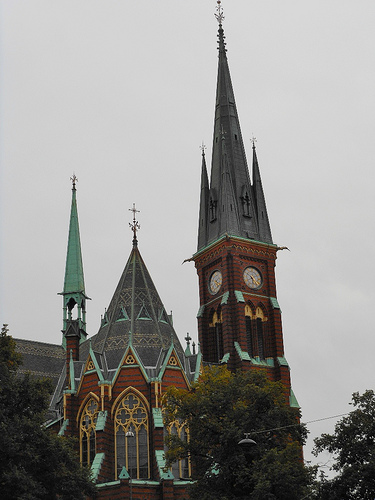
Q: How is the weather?
A: It is overcast.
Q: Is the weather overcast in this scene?
A: Yes, it is overcast.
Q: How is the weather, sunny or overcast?
A: It is overcast.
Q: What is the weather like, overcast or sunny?
A: It is overcast.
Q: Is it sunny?
A: No, it is overcast.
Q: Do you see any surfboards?
A: No, there are no surfboards.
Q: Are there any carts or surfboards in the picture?
A: No, there are no surfboards or carts.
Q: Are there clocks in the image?
A: Yes, there is a clock.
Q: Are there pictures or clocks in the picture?
A: Yes, there is a clock.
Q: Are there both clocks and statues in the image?
A: No, there is a clock but no statues.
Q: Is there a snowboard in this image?
A: No, there are no snowboards.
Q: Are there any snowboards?
A: No, there are no snowboards.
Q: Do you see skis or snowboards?
A: No, there are no snowboards or skis.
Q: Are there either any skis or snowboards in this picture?
A: No, there are no snowboards or skis.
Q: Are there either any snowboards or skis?
A: No, there are no snowboards or skis.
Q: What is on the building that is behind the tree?
A: The clock is on the building.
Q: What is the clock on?
A: The clock is on the building.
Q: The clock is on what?
A: The clock is on the building.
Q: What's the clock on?
A: The clock is on the building.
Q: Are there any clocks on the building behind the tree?
A: Yes, there is a clock on the building.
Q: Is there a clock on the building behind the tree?
A: Yes, there is a clock on the building.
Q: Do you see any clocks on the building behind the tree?
A: Yes, there is a clock on the building.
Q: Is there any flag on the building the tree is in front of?
A: No, there is a clock on the building.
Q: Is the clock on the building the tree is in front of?
A: Yes, the clock is on the building.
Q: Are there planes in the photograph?
A: No, there are no planes.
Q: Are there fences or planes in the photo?
A: No, there are no planes or fences.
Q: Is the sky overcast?
A: Yes, the sky is overcast.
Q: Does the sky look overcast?
A: Yes, the sky is overcast.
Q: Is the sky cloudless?
A: No, the sky is overcast.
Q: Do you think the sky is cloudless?
A: No, the sky is overcast.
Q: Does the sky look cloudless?
A: No, the sky is overcast.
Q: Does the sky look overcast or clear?
A: The sky is overcast.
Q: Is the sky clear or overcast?
A: The sky is overcast.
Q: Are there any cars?
A: No, there are no cars.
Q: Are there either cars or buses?
A: No, there are no cars or buses.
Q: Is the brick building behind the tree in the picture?
A: Yes, the building is behind the tree.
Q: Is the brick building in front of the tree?
A: No, the building is behind the tree.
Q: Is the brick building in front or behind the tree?
A: The building is behind the tree.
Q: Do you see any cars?
A: No, there are no cars.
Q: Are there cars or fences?
A: No, there are no cars or fences.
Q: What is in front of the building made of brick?
A: The tree is in front of the building.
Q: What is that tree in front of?
A: The tree is in front of the building.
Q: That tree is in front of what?
A: The tree is in front of the building.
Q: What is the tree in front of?
A: The tree is in front of the building.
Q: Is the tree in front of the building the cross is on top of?
A: Yes, the tree is in front of the building.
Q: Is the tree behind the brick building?
A: No, the tree is in front of the building.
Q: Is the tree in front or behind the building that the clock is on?
A: The tree is in front of the building.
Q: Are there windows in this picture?
A: Yes, there is a window.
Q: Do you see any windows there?
A: Yes, there is a window.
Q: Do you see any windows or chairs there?
A: Yes, there is a window.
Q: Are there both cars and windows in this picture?
A: No, there is a window but no cars.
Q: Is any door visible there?
A: No, there are no doors.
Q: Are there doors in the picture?
A: No, there are no doors.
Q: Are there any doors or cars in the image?
A: No, there are no doors or cars.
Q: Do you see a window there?
A: Yes, there is a window.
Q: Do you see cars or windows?
A: Yes, there is a window.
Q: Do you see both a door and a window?
A: No, there is a window but no doors.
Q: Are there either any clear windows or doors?
A: Yes, there is a clear window.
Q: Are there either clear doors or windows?
A: Yes, there is a clear window.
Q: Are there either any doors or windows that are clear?
A: Yes, the window is clear.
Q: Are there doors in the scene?
A: No, there are no doors.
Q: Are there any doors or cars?
A: No, there are no doors or cars.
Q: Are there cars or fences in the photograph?
A: No, there are no cars or fences.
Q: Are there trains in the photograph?
A: No, there are no trains.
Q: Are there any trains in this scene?
A: No, there are no trains.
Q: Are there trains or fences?
A: No, there are no trains or fences.